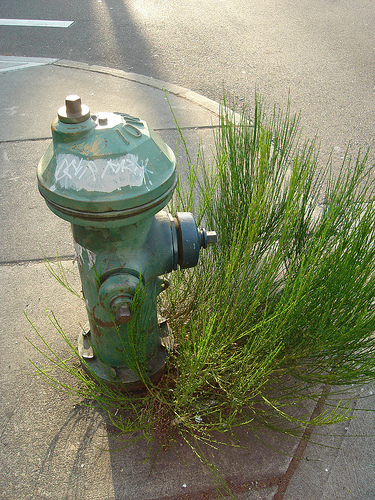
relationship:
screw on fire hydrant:
[205, 231, 217, 246] [37, 94, 217, 393]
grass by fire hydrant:
[167, 85, 372, 467] [37, 94, 217, 393]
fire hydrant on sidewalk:
[37, 94, 217, 393] [0, 54, 374, 499]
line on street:
[0, 19, 73, 28] [0, 1, 375, 237]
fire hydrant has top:
[37, 94, 217, 393] [38, 93, 178, 210]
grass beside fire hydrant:
[167, 85, 372, 467] [37, 94, 217, 393]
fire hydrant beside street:
[37, 94, 217, 393] [0, 1, 375, 237]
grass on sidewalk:
[167, 85, 372, 467] [0, 54, 374, 499]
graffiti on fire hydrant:
[53, 156, 153, 188] [37, 94, 217, 393]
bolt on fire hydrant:
[65, 95, 84, 112] [37, 94, 217, 393]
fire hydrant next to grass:
[37, 94, 217, 393] [167, 85, 372, 467]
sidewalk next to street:
[0, 54, 374, 499] [0, 1, 375, 237]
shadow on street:
[1, 1, 167, 78] [0, 1, 375, 237]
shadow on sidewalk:
[104, 388, 373, 498] [0, 54, 374, 499]